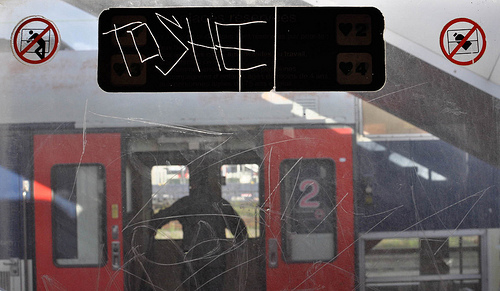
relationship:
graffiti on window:
[108, 8, 270, 78] [0, 3, 499, 289]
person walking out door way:
[162, 156, 241, 280] [122, 132, 267, 290]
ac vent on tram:
[293, 96, 318, 119] [3, 46, 500, 285]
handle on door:
[268, 236, 278, 268] [263, 123, 361, 290]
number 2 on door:
[298, 179, 322, 209] [263, 123, 361, 290]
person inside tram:
[162, 156, 241, 280] [3, 46, 500, 285]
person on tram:
[162, 156, 241, 280] [3, 46, 500, 285]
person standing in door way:
[162, 156, 241, 280] [122, 132, 267, 290]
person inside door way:
[162, 156, 241, 280] [122, 132, 267, 290]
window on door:
[281, 159, 338, 259] [263, 123, 361, 290]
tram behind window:
[3, 46, 500, 285] [0, 3, 499, 289]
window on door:
[0, 3, 499, 289] [263, 123, 361, 290]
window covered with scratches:
[0, 3, 499, 289] [144, 211, 256, 277]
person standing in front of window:
[162, 156, 241, 280] [0, 3, 499, 289]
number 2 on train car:
[298, 179, 318, 209] [0, 48, 360, 289]